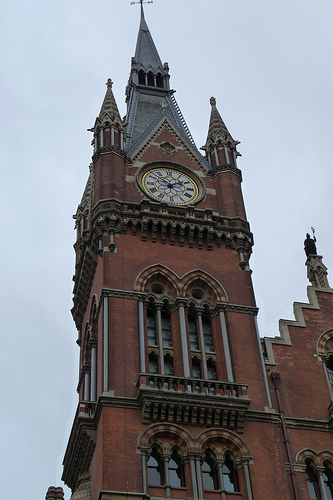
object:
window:
[206, 358, 217, 395]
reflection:
[205, 453, 218, 488]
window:
[201, 452, 219, 490]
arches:
[133, 263, 181, 297]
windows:
[202, 312, 215, 352]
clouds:
[16, 60, 67, 123]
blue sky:
[0, 1, 332, 499]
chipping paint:
[275, 345, 297, 367]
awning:
[195, 428, 253, 460]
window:
[147, 442, 164, 485]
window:
[146, 304, 158, 346]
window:
[160, 299, 172, 347]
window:
[148, 351, 159, 389]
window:
[163, 353, 176, 390]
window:
[192, 355, 206, 393]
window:
[168, 443, 185, 488]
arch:
[137, 422, 194, 456]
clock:
[142, 168, 199, 205]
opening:
[138, 68, 146, 86]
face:
[146, 169, 193, 201]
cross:
[129, 0, 154, 18]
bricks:
[258, 425, 280, 495]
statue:
[304, 224, 317, 257]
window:
[152, 283, 163, 293]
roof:
[304, 225, 331, 287]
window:
[202, 303, 215, 352]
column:
[103, 297, 108, 392]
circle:
[154, 175, 187, 197]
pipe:
[268, 369, 299, 498]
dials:
[155, 176, 184, 195]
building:
[45, 0, 332, 499]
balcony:
[135, 370, 252, 433]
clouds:
[204, 11, 282, 67]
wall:
[96, 403, 333, 499]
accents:
[136, 160, 207, 206]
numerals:
[147, 171, 194, 201]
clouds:
[2, 302, 64, 386]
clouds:
[195, 30, 307, 91]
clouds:
[251, 68, 328, 178]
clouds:
[7, 27, 99, 123]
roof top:
[54, 2, 332, 414]